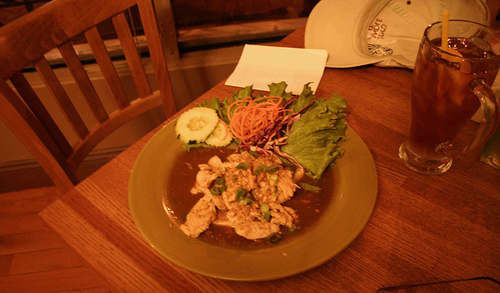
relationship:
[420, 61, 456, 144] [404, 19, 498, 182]
tea in glass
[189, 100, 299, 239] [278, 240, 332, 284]
food on plate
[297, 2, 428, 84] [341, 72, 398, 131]
cap on table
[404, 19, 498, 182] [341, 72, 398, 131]
glass on table